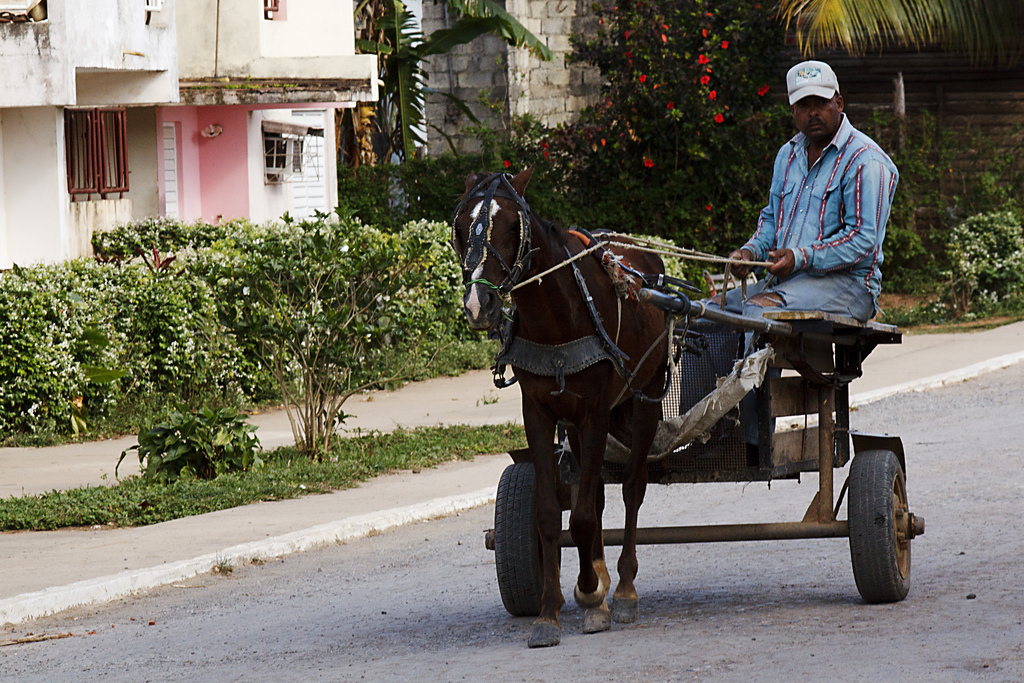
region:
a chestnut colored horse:
[452, 163, 674, 647]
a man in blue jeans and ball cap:
[673, 58, 909, 441]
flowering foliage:
[495, 1, 781, 230]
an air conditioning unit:
[264, 122, 309, 179]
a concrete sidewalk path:
[0, 368, 517, 638]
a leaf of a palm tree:
[768, 5, 1019, 53]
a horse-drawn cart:
[476, 308, 928, 625]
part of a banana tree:
[353, 1, 560, 199]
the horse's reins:
[464, 235, 772, 296]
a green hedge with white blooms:
[0, 215, 497, 432]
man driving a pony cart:
[442, 49, 932, 640]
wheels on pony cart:
[487, 455, 927, 611]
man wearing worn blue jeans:
[705, 59, 911, 354]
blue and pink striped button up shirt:
[762, 110, 906, 335]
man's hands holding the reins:
[533, 156, 832, 310]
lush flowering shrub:
[520, 0, 770, 227]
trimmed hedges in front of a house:
[0, 212, 479, 434]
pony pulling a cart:
[435, 150, 667, 652]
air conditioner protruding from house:
[255, 114, 326, 188]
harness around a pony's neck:
[438, 151, 641, 391]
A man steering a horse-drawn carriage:
[450, 57, 932, 653]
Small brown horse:
[449, 155, 685, 655]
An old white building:
[0, 0, 378, 270]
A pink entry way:
[156, 96, 353, 220]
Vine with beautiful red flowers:
[471, 0, 786, 257]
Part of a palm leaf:
[766, 1, 1020, 65]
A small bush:
[219, 206, 442, 467]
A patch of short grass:
[0, 422, 532, 525]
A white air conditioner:
[264, 134, 306, 185]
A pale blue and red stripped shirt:
[735, 148, 913, 298]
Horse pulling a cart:
[427, 167, 788, 655]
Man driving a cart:
[740, 70, 950, 375]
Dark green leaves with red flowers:
[614, 16, 744, 193]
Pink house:
[149, 98, 282, 239]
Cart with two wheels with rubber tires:
[441, 325, 980, 640]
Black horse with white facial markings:
[422, 174, 635, 443]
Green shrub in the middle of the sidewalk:
[178, 199, 511, 509]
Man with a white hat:
[751, 36, 917, 373]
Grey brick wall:
[430, 9, 595, 143]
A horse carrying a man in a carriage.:
[424, 168, 713, 611]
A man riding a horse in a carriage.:
[634, 53, 933, 439]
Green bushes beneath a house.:
[70, 142, 424, 472]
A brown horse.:
[422, 164, 729, 673]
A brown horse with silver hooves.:
[403, 165, 704, 655]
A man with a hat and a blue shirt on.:
[686, 66, 955, 403]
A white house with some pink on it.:
[19, 7, 387, 249]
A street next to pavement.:
[190, 505, 473, 677]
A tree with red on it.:
[544, 25, 763, 190]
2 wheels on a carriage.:
[360, 412, 939, 638]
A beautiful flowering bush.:
[569, 4, 789, 284]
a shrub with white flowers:
[19, 286, 432, 442]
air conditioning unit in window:
[259, 134, 305, 185]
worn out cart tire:
[844, 446, 928, 608]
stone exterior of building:
[417, 0, 610, 165]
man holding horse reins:
[692, 57, 901, 327]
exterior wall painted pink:
[157, 105, 252, 227]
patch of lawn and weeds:
[2, 424, 527, 533]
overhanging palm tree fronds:
[777, 1, 978, 60]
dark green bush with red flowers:
[499, 4, 778, 252]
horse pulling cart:
[446, 165, 674, 652]